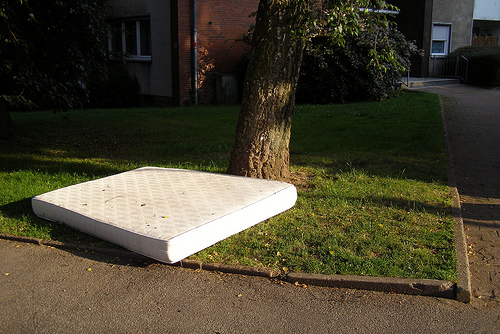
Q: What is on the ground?
A: A mattress.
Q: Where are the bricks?
A: On the building.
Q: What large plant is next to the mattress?
A: A tree.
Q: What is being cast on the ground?
A: Shadows.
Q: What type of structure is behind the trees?
A: A building.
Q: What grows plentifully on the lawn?
A: Grass.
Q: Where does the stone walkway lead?
A: To the building.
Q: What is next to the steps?
A: A bush.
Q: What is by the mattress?
A: A tree.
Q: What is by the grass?
A: Asphalt road.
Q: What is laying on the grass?
A: A mattress.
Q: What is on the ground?
A: A mattress.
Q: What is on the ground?
A: Grass.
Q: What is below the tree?
A: A mattress.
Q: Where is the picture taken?
A: The yard.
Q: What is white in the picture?
A: A mattress.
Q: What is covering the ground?
A: Grass.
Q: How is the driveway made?
A: Of concrete.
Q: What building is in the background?
A: A house.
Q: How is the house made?
A: Of brick.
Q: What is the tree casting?
A: A shadow.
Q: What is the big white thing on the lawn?
A: A mattress.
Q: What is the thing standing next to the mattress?
A: A tree.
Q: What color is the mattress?
A: White.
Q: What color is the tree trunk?
A: Brown.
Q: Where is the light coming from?
A: The sun.